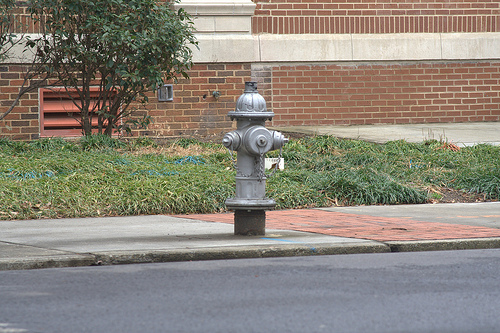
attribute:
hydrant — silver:
[203, 67, 291, 236]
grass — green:
[84, 173, 122, 200]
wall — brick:
[323, 84, 363, 114]